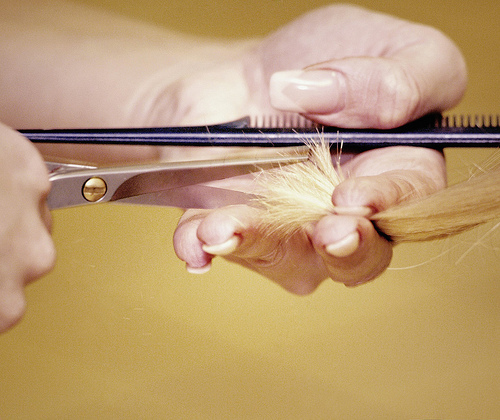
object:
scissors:
[43, 155, 311, 212]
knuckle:
[368, 57, 424, 130]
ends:
[246, 122, 344, 243]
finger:
[265, 0, 467, 131]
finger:
[171, 203, 215, 278]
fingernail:
[266, 67, 348, 115]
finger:
[195, 200, 328, 296]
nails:
[320, 228, 362, 258]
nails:
[200, 232, 243, 256]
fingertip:
[328, 177, 384, 219]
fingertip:
[309, 212, 372, 257]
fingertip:
[194, 206, 249, 256]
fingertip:
[170, 223, 214, 276]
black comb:
[12, 111, 500, 148]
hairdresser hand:
[156, 2, 470, 298]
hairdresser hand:
[0, 119, 58, 335]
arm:
[0, 0, 249, 167]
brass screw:
[80, 175, 110, 203]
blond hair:
[202, 120, 500, 271]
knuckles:
[16, 221, 58, 284]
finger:
[329, 144, 448, 217]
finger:
[309, 210, 393, 288]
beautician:
[0, 0, 468, 337]